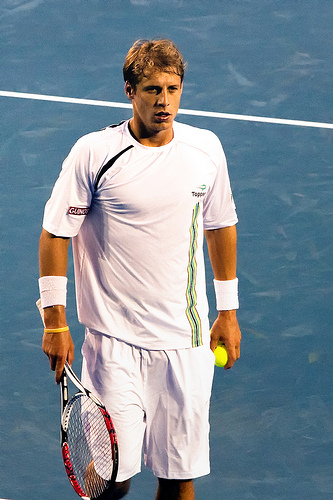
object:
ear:
[124, 78, 133, 102]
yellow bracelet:
[43, 322, 71, 335]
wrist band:
[212, 275, 240, 311]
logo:
[192, 180, 209, 200]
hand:
[42, 327, 74, 385]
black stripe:
[94, 142, 133, 194]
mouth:
[155, 109, 173, 119]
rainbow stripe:
[186, 200, 204, 346]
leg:
[155, 476, 196, 499]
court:
[0, 0, 333, 499]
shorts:
[80, 328, 215, 480]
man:
[39, 37, 241, 499]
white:
[104, 189, 162, 302]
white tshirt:
[41, 120, 238, 350]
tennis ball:
[213, 342, 229, 367]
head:
[123, 36, 185, 131]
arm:
[204, 132, 238, 317]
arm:
[38, 135, 96, 323]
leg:
[81, 457, 131, 498]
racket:
[34, 299, 120, 499]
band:
[39, 273, 68, 306]